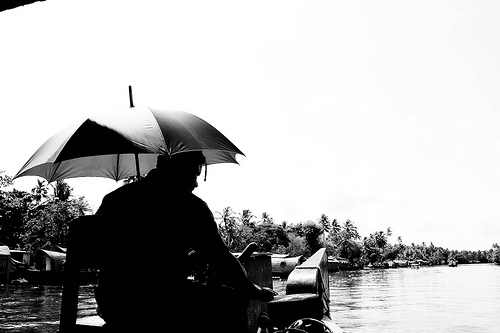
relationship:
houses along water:
[217, 209, 498, 274] [329, 261, 499, 330]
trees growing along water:
[3, 169, 499, 275] [329, 261, 499, 330]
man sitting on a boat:
[82, 150, 278, 332] [16, 232, 337, 332]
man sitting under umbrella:
[82, 150, 278, 332] [10, 83, 246, 183]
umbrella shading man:
[10, 83, 246, 183] [82, 150, 278, 332]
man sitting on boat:
[82, 150, 278, 332] [16, 232, 337, 332]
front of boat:
[273, 243, 336, 332] [16, 232, 337, 332]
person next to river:
[76, 151, 278, 332] [320, 257, 496, 330]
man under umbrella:
[82, 150, 278, 332] [10, 83, 246, 183]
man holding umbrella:
[82, 150, 278, 332] [10, 83, 246, 183]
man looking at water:
[82, 150, 278, 332] [329, 261, 499, 330]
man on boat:
[82, 150, 278, 332] [16, 232, 337, 332]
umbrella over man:
[10, 83, 246, 183] [82, 150, 278, 332]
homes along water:
[231, 246, 462, 274] [329, 261, 499, 330]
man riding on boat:
[82, 150, 278, 332] [16, 232, 337, 332]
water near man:
[329, 261, 499, 330] [82, 150, 278, 332]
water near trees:
[329, 261, 499, 330] [3, 169, 499, 275]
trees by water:
[3, 169, 499, 275] [329, 261, 499, 330]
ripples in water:
[3, 283, 111, 332] [329, 261, 499, 330]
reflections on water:
[333, 265, 404, 314] [329, 261, 499, 330]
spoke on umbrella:
[239, 148, 247, 162] [10, 83, 246, 183]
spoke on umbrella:
[162, 148, 176, 162] [10, 83, 246, 183]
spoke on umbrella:
[49, 157, 62, 168] [10, 83, 246, 183]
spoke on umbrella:
[7, 175, 17, 188] [10, 83, 246, 183]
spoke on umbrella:
[43, 177, 54, 188] [10, 83, 246, 183]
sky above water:
[0, 1, 500, 247] [329, 261, 499, 330]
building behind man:
[0, 2, 40, 18] [82, 150, 278, 332]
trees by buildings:
[3, 169, 499, 275] [262, 249, 439, 271]